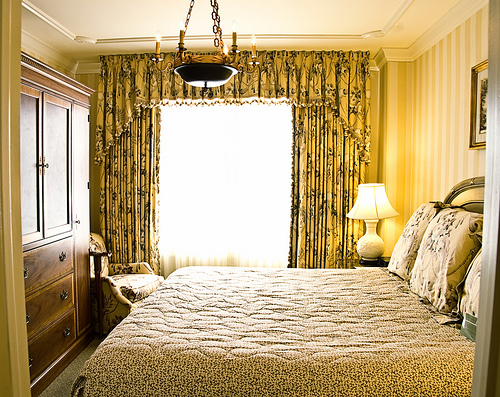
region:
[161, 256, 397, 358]
Comfertor on a bed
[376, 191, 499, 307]
Pillows by a wall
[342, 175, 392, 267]
White lamp on a stand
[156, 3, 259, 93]
Lamp above a bed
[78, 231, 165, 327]
Chair in the corner of a room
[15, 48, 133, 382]
Brown chest in a room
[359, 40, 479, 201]
Stripped wall paper on a wall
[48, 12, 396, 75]
Crown molding on a ceiling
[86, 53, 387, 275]
Curtains on a window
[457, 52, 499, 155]
Picture on a wall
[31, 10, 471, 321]
a fancy bedroom at a home or hotel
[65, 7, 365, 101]
a lamp on the cieling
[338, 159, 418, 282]
a lamp by the bed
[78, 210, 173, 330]
a chair by the corner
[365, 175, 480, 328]
pillows on the bed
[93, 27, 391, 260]
nice curtains on the window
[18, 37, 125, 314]
a cabiinet along the wall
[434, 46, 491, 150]
a picture on the wall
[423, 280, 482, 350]
something green on the wall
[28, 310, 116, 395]
a green rug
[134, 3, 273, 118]
Black light hanging from ceiling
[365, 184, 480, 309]
Decorative pillow cases on pillows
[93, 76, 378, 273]
Decorative curtains by the window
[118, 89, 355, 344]
Sunlight shining in the room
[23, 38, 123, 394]
Lovely wood stained dresser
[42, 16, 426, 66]
Decorative molding on the ceiling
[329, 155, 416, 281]
Lamp on the table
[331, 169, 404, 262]
Round lamp with dainty lamp shade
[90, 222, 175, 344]
Chair in the corner of the room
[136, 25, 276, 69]
Candle style lights on chandelier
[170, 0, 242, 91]
the celling light is black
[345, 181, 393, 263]
the lamp sitting on the stand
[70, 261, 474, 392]
the compfort is gold and black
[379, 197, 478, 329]
the pillows is gold and black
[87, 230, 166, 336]
matching chair to match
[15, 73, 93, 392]
a brown tall chest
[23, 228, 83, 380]
the chest have three draws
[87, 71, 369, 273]
black to match the set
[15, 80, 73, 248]
there are two door on the chest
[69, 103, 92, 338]
there are one tall door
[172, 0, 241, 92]
black light hanging from the ceiling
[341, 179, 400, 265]
white lamp and shade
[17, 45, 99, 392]
brown wood dresser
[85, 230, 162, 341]
white and black chair in the corner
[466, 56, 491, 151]
picture on the wall with gold frame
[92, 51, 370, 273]
yellow and black curtains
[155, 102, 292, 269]
sheer white curtains on the window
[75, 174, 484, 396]
bed taking up most of the room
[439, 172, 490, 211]
gray and white headboard